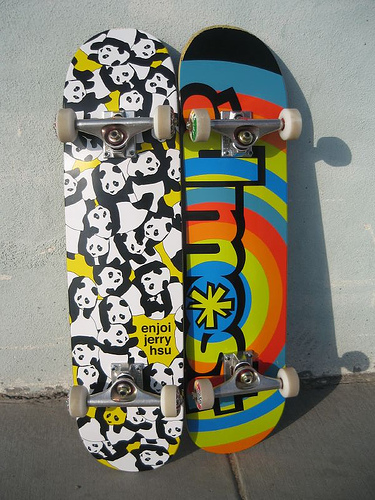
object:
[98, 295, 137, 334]
panda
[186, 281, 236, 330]
asterisk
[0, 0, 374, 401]
wall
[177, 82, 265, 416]
lettering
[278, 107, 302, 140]
wheel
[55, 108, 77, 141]
wheel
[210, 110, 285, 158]
holder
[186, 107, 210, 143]
wheel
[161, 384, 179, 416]
wheel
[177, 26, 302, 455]
skate board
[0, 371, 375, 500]
ground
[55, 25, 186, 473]
board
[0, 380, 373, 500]
sidewalk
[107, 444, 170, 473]
panda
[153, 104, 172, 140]
wheel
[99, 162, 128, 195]
head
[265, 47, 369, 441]
shadow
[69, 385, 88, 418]
wheel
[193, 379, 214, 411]
wheel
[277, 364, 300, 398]
wheel